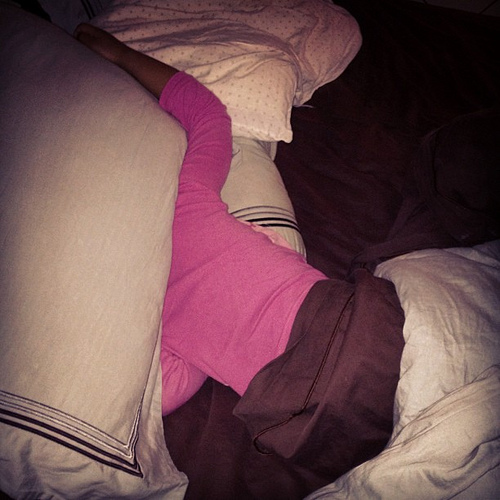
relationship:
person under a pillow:
[73, 22, 500, 416] [2, 5, 187, 500]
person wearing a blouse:
[73, 22, 500, 416] [158, 70, 324, 416]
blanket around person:
[295, 242, 498, 499] [73, 22, 500, 416]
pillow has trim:
[2, 5, 187, 500] [0, 406, 145, 481]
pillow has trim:
[2, 5, 187, 500] [247, 217, 303, 236]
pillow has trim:
[2, 5, 187, 500] [0, 393, 142, 462]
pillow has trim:
[2, 5, 187, 500] [227, 204, 294, 218]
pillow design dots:
[93, 2, 363, 145] [81, 3, 364, 143]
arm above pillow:
[79, 24, 232, 218] [2, 5, 187, 500]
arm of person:
[79, 24, 232, 218] [73, 22, 500, 416]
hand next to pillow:
[72, 23, 126, 59] [2, 5, 187, 500]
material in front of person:
[93, 2, 363, 145] [73, 22, 500, 416]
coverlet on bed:
[295, 242, 498, 499] [4, 3, 499, 495]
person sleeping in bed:
[73, 22, 500, 416] [4, 3, 499, 495]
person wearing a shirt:
[73, 22, 500, 416] [158, 70, 324, 416]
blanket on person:
[232, 1, 498, 499] [73, 22, 500, 416]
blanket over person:
[295, 242, 498, 499] [73, 22, 500, 416]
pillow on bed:
[2, 5, 187, 500] [4, 3, 499, 495]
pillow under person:
[2, 5, 187, 500] [73, 22, 500, 416]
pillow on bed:
[93, 2, 363, 145] [4, 3, 499, 495]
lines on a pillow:
[0, 389, 147, 483] [2, 5, 187, 500]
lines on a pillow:
[231, 205, 300, 234] [2, 5, 187, 500]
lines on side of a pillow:
[0, 389, 147, 483] [2, 5, 187, 500]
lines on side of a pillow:
[231, 205, 300, 234] [4, 7, 309, 496]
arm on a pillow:
[79, 24, 232, 218] [2, 5, 187, 500]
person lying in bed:
[73, 22, 500, 416] [4, 3, 499, 495]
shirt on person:
[158, 70, 324, 416] [73, 22, 500, 416]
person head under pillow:
[73, 22, 500, 416] [2, 5, 187, 500]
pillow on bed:
[4, 7, 309, 496] [4, 3, 499, 495]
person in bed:
[73, 22, 500, 416] [4, 3, 499, 495]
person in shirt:
[73, 22, 500, 416] [158, 70, 324, 416]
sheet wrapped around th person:
[232, 1, 498, 499] [73, 22, 500, 416]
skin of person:
[74, 23, 176, 99] [73, 22, 500, 416]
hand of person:
[72, 23, 126, 59] [73, 22, 500, 416]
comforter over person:
[295, 242, 498, 499] [73, 22, 500, 416]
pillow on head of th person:
[2, 5, 187, 500] [73, 22, 500, 416]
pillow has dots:
[93, 2, 363, 145] [81, 3, 364, 143]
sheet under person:
[232, 1, 498, 499] [73, 22, 500, 416]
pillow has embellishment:
[2, 5, 187, 500] [224, 207, 303, 230]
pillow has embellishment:
[2, 5, 187, 500] [0, 390, 146, 477]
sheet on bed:
[232, 1, 498, 499] [4, 3, 499, 495]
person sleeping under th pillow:
[73, 22, 500, 416] [2, 5, 187, 500]